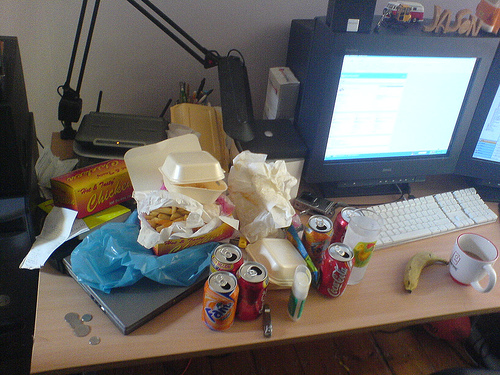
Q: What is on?
A: The computer.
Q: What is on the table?
A: Drinks.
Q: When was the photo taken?
A: Daytime.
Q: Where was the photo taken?
A: At the home office.